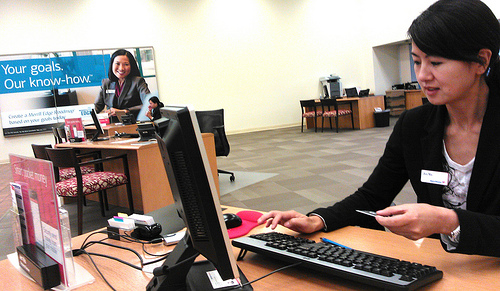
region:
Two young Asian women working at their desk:
[100, 7, 485, 98]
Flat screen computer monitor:
[148, 105, 238, 280]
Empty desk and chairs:
[296, 95, 371, 131]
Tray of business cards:
[112, 210, 148, 221]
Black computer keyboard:
[288, 247, 389, 262]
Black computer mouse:
[227, 213, 238, 223]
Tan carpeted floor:
[252, 135, 368, 166]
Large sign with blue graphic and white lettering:
[6, 62, 91, 99]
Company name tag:
[425, 170, 440, 180]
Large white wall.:
[172, 13, 312, 86]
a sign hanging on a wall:
[2, 41, 97, 143]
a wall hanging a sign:
[1, 41, 44, 141]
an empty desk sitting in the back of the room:
[296, 59, 362, 125]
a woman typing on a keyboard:
[260, 192, 325, 289]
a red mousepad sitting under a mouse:
[220, 197, 255, 239]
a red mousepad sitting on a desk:
[217, 182, 269, 240]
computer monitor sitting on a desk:
[136, 98, 273, 290]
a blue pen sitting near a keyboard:
[301, 228, 340, 268]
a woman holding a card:
[345, 177, 402, 234]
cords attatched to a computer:
[96, 222, 167, 282]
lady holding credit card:
[246, 11, 498, 281]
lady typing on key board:
[240, 165, 358, 282]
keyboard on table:
[223, 202, 467, 289]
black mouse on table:
[217, 200, 269, 252]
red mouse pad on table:
[223, 201, 276, 258]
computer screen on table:
[131, 85, 251, 290]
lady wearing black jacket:
[289, 88, 499, 263]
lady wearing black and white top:
[418, 147, 491, 230]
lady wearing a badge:
[417, 147, 477, 209]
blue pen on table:
[312, 227, 382, 275]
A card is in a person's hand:
[345, 169, 447, 244]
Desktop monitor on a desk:
[141, 100, 249, 288]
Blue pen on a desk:
[319, 237, 358, 253]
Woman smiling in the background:
[98, 45, 151, 125]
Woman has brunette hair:
[99, 42, 157, 112]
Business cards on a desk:
[108, 210, 150, 233]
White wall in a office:
[201, 32, 303, 85]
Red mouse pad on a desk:
[243, 208, 257, 228]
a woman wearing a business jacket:
[255, 0, 499, 259]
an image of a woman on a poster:
[92, 48, 152, 118]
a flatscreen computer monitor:
[153, 103, 240, 282]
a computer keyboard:
[229, 229, 444, 290]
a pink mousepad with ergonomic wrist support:
[225, 208, 268, 239]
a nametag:
[418, 167, 450, 187]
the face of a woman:
[407, 0, 499, 108]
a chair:
[43, 145, 136, 236]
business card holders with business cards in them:
[104, 209, 164, 242]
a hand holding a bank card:
[352, 199, 460, 241]